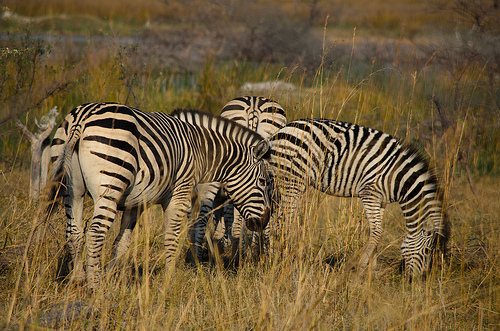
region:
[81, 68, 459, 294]
These are many zebras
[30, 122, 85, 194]
This is a tail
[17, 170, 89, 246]
The tail is fluffy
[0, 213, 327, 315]
The grass is long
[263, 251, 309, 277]
The grass is parched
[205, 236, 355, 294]
The grass is yellow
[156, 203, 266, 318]
The legs are long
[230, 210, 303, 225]
This is a mouth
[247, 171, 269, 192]
This is an eye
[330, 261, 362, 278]
This is a hoof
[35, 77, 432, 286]
three zebras standing in a field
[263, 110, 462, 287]
a zebra grazing in a field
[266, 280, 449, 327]
long tan grass in the field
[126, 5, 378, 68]
a dead tree in the distance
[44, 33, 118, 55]
a river in the distance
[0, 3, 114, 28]
a dead tree laying on the ground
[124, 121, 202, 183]
black and white stripes of the zebra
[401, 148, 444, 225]
black and white mane of the zebra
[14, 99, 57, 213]
grey tree trunk sticking out of the ground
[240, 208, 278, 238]
black nose and mouth of the zebra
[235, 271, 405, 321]
long yellow grass of the field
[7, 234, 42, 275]
brown dirt of the ground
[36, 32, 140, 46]
a river in the distance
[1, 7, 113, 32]
a fallen tree trunk on the ground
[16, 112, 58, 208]
a dead tree tunk sticking out of the ground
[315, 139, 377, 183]
black and white stripes of the zebra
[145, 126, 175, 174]
black and white stripes on a zebra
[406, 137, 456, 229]
the mane on a zebra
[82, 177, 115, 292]
the right rear leg of a zebra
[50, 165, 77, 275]
the left rear leg of a zebra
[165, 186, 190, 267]
the right front leg of a zebra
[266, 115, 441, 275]
a zebra eating grass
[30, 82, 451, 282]
a group a zebras standing together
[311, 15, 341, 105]
a blade of tall brown grass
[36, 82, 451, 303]
zebras standing among tall grass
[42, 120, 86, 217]
the tail of a zebra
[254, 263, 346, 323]
this is the grass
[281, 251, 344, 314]
the grass is green in color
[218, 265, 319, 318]
the grass is tall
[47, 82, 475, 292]
these are some zebras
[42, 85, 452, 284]
the zebras are eating grass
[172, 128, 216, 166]
the fur is white and black in color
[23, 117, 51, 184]
this is a piece of wood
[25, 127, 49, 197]
the wood is brown in color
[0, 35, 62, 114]
this is a branch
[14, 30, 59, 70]
the leaves are small